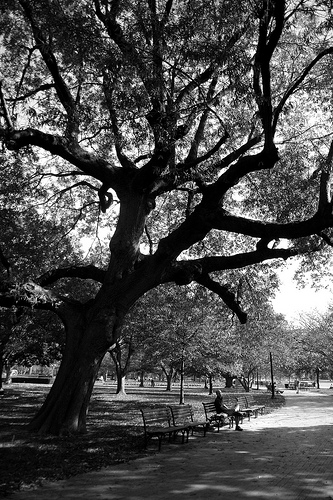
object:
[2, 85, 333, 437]
tree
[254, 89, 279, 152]
branch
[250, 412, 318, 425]
pathway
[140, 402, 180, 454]
bench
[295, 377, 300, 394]
person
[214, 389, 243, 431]
person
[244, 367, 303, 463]
trail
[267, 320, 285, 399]
light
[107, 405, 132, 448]
grass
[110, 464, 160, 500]
path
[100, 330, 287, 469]
park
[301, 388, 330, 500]
sidewalk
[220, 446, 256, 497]
walkway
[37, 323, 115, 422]
trunk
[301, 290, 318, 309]
sky